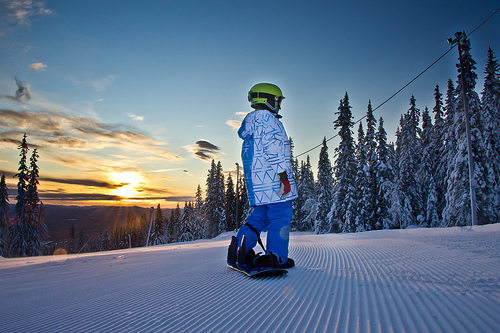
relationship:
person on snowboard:
[230, 82, 299, 269] [225, 246, 287, 278]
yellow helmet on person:
[248, 82, 286, 110] [227, 77, 303, 276]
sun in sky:
[97, 160, 152, 211] [72, 6, 196, 117]